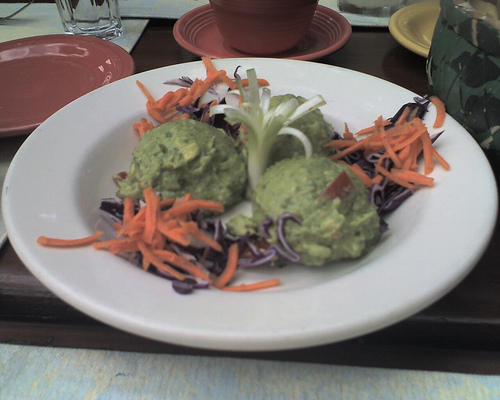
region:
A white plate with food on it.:
[2, 55, 499, 352]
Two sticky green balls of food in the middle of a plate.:
[123, 118, 380, 265]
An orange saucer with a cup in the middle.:
[173, 0, 353, 60]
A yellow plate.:
[388, 0, 444, 56]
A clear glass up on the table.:
[51, 0, 124, 40]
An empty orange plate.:
[0, 31, 134, 137]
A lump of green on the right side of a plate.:
[247, 158, 384, 268]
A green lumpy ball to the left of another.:
[118, 123, 245, 215]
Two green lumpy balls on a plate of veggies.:
[124, 118, 380, 267]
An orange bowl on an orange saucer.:
[211, 0, 320, 56]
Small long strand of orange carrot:
[36, 231, 108, 248]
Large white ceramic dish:
[4, 58, 499, 353]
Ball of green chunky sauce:
[226, 156, 384, 268]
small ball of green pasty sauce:
[113, 120, 249, 216]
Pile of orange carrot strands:
[325, 92, 450, 191]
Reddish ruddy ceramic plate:
[0, 34, 134, 136]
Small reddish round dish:
[211, 0, 321, 55]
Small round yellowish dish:
[389, 0, 445, 57]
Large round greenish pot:
[426, 0, 499, 162]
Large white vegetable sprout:
[211, 64, 327, 197]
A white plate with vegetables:
[1, 56, 497, 351]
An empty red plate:
[0, 32, 136, 139]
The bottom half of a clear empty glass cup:
[52, 0, 124, 43]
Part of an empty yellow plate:
[387, 0, 442, 58]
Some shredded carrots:
[37, 186, 282, 294]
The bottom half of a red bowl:
[210, 0, 319, 55]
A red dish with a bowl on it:
[170, 0, 351, 61]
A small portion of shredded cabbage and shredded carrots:
[322, 93, 450, 214]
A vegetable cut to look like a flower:
[207, 68, 324, 197]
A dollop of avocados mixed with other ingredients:
[250, 157, 380, 267]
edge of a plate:
[345, 319, 392, 345]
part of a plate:
[241, 307, 277, 356]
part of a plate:
[305, 308, 364, 370]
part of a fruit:
[311, 240, 347, 280]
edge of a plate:
[231, 300, 285, 370]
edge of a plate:
[263, 323, 307, 375]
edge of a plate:
[296, 317, 333, 353]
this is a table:
[76, 370, 115, 382]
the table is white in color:
[93, 365, 135, 383]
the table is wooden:
[51, 358, 106, 383]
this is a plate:
[233, 300, 294, 332]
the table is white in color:
[266, 298, 327, 328]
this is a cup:
[243, 10, 298, 37]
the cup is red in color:
[235, 3, 266, 20]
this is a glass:
[71, 5, 117, 31]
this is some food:
[156, 120, 374, 233]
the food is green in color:
[290, 167, 315, 193]